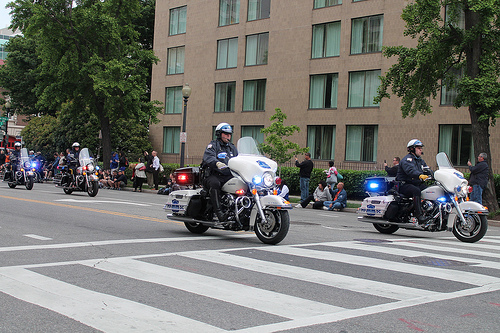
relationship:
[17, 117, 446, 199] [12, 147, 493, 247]
cops on bikes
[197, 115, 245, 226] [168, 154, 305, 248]
cop on bike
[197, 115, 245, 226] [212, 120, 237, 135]
cop in helmet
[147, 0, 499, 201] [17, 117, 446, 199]
building behind cops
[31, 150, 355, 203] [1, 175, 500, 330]
people on street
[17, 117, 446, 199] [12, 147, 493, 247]
cops on their bikes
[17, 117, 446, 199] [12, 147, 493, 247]
cops on top of bikes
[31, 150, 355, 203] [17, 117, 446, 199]
people watching cops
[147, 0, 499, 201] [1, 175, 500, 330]
building near street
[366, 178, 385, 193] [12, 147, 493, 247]
light on bikes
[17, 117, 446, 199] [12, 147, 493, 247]
cops on top their bikes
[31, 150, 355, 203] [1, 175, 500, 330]
people on top of street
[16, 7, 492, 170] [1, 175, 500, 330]
trees near street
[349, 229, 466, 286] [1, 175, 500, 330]
hole in street